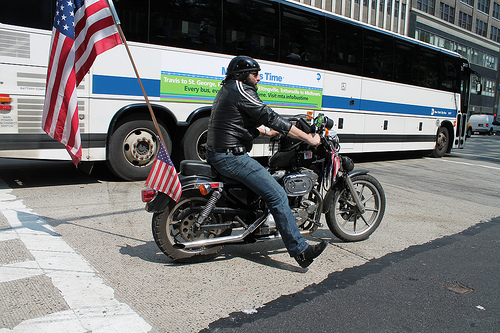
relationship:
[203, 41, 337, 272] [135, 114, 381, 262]
man on bike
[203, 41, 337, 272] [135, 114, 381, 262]
man riding bike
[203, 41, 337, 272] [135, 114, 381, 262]
man using bike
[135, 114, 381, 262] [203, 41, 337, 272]
bike under man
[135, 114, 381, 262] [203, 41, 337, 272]
bike below man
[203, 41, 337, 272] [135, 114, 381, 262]
man above bike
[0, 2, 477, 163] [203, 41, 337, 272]
bus close to man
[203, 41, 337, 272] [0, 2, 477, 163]
man close to bus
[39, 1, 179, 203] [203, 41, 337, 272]
flag beside man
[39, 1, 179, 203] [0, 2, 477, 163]
flag beside bus